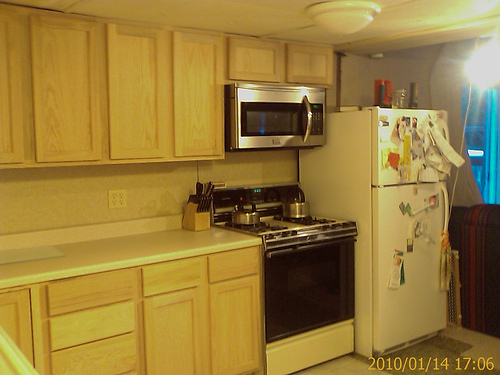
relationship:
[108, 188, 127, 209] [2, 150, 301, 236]
socket on wall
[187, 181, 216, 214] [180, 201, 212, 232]
knives in knife block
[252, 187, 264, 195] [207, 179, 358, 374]
time on oven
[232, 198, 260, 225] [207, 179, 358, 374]
tea kettle on oven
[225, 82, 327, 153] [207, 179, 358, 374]
microwave above oven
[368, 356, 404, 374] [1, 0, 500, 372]
2010 on photo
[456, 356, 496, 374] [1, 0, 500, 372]
17:06 on photo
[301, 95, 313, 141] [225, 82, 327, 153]
handle on microwave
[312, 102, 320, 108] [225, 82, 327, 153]
time on microwave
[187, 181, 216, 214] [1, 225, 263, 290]
knives on counter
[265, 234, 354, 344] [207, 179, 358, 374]
door on oven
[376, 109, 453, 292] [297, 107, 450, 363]
objects on refrigerator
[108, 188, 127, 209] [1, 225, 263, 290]
socket above counter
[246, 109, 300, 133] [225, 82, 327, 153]
window on door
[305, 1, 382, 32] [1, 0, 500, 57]
light on ceiling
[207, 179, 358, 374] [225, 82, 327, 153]
oven below microwave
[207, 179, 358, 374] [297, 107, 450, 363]
oven next to refrigerator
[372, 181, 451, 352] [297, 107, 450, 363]
door on refrigerator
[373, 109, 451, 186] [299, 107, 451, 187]
door on freezer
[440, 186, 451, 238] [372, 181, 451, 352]
handle on door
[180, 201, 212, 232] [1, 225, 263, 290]
knife block on counter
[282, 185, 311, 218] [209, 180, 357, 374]
tea kettle on stove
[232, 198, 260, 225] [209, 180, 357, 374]
tea kettle on stove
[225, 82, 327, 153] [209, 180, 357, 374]
microwave over stove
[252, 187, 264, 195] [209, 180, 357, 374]
time on stove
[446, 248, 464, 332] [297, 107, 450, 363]
gate leaning on refrigerator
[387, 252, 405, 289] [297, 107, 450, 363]
paper on refrigerator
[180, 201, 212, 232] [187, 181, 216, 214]
knife block has knives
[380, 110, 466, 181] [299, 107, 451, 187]
papers on freezer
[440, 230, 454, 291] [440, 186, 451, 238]
hand towel hanging from handle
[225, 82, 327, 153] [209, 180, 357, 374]
microwave above stove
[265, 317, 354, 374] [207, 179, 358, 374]
storage drawer under oven